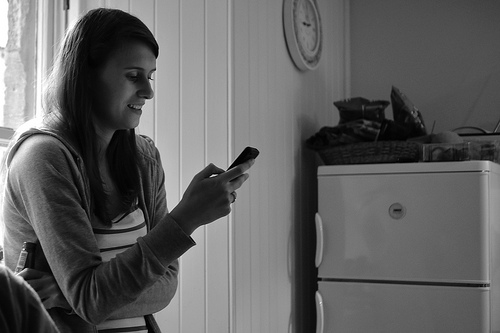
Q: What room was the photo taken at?
A: It was taken at the kitchen.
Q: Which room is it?
A: It is a kitchen.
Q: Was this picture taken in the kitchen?
A: Yes, it was taken in the kitchen.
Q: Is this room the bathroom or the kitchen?
A: It is the kitchen.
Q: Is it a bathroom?
A: No, it is a kitchen.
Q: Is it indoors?
A: Yes, it is indoors.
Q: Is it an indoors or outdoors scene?
A: It is indoors.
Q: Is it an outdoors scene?
A: No, it is indoors.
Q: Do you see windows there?
A: Yes, there is a window.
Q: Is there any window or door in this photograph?
A: Yes, there is a window.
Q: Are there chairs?
A: No, there are no chairs.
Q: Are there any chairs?
A: No, there are no chairs.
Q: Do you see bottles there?
A: Yes, there is a bottle.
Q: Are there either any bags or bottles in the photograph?
A: Yes, there is a bottle.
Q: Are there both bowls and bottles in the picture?
A: No, there is a bottle but no bowls.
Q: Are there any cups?
A: No, there are no cups.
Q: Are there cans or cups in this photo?
A: No, there are no cups or cans.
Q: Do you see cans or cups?
A: No, there are no cups or cans.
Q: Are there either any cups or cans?
A: No, there are no cups or cans.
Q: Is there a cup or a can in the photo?
A: No, there are no cups or cans.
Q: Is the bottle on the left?
A: Yes, the bottle is on the left of the image.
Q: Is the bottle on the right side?
A: No, the bottle is on the left of the image.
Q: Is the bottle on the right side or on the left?
A: The bottle is on the left of the image.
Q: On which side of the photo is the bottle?
A: The bottle is on the left of the image.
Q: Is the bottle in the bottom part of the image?
A: Yes, the bottle is in the bottom of the image.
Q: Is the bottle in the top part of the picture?
A: No, the bottle is in the bottom of the image.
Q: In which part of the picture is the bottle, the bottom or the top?
A: The bottle is in the bottom of the image.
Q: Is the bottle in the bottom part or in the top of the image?
A: The bottle is in the bottom of the image.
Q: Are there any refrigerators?
A: Yes, there is a refrigerator.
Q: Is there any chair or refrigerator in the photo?
A: Yes, there is a refrigerator.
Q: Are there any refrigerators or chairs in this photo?
A: Yes, there is a refrigerator.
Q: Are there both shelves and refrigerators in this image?
A: No, there is a refrigerator but no shelves.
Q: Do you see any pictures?
A: No, there are no pictures.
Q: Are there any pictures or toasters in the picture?
A: No, there are no pictures or toasters.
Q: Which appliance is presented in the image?
A: The appliance is a refrigerator.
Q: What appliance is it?
A: The appliance is a refrigerator.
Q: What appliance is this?
A: This is a refrigerator.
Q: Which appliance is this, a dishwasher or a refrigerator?
A: This is a refrigerator.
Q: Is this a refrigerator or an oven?
A: This is a refrigerator.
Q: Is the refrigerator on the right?
A: Yes, the refrigerator is on the right of the image.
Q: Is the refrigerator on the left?
A: No, the refrigerator is on the right of the image.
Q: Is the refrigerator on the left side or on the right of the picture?
A: The refrigerator is on the right of the image.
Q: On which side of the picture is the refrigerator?
A: The refrigerator is on the right of the image.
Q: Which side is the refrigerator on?
A: The refrigerator is on the right of the image.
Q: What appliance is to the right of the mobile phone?
A: The appliance is a refrigerator.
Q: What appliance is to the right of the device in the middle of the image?
A: The appliance is a refrigerator.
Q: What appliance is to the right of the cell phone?
A: The appliance is a refrigerator.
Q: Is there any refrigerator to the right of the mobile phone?
A: Yes, there is a refrigerator to the right of the mobile phone.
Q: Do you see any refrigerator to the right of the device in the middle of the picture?
A: Yes, there is a refrigerator to the right of the mobile phone.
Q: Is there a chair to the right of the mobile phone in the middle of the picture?
A: No, there is a refrigerator to the right of the cell phone.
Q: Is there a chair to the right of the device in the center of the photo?
A: No, there is a refrigerator to the right of the cell phone.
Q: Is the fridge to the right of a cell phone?
A: Yes, the fridge is to the right of a cell phone.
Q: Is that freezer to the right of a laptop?
A: No, the freezer is to the right of a cell phone.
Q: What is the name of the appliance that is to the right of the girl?
A: The appliance is a refrigerator.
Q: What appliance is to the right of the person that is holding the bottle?
A: The appliance is a refrigerator.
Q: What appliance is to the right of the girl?
A: The appliance is a refrigerator.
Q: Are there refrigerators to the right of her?
A: Yes, there is a refrigerator to the right of the girl.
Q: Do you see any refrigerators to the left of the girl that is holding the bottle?
A: No, the refrigerator is to the right of the girl.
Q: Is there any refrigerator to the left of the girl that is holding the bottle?
A: No, the refrigerator is to the right of the girl.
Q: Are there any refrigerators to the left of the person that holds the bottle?
A: No, the refrigerator is to the right of the girl.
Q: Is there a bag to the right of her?
A: No, there is a refrigerator to the right of the girl.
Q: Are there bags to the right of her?
A: No, there is a refrigerator to the right of the girl.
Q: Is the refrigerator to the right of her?
A: Yes, the refrigerator is to the right of the girl.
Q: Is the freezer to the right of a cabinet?
A: No, the freezer is to the right of the girl.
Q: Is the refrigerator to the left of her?
A: No, the refrigerator is to the right of the girl.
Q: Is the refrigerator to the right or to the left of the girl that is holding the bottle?
A: The refrigerator is to the right of the girl.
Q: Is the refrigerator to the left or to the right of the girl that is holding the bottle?
A: The refrigerator is to the right of the girl.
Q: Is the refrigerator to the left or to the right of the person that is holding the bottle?
A: The refrigerator is to the right of the girl.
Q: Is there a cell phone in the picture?
A: Yes, there is a cell phone.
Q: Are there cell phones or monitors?
A: Yes, there is a cell phone.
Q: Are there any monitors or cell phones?
A: Yes, there is a cell phone.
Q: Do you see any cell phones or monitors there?
A: Yes, there is a cell phone.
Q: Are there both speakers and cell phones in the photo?
A: No, there is a cell phone but no speakers.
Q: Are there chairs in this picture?
A: No, there are no chairs.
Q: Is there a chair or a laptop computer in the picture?
A: No, there are no chairs or laptops.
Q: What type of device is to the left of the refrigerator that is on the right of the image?
A: The device is a cell phone.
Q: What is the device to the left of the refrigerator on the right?
A: The device is a cell phone.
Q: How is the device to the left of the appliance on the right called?
A: The device is a cell phone.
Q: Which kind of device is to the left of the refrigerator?
A: The device is a cell phone.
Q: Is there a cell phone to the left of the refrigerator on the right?
A: Yes, there is a cell phone to the left of the fridge.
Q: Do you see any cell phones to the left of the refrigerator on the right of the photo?
A: Yes, there is a cell phone to the left of the fridge.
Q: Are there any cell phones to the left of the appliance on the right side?
A: Yes, there is a cell phone to the left of the fridge.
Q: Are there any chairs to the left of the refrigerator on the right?
A: No, there is a cell phone to the left of the fridge.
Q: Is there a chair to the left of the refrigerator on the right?
A: No, there is a cell phone to the left of the fridge.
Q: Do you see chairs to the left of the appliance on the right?
A: No, there is a cell phone to the left of the fridge.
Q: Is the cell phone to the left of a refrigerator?
A: Yes, the cell phone is to the left of a refrigerator.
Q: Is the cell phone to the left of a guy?
A: No, the cell phone is to the left of a refrigerator.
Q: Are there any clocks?
A: Yes, there is a clock.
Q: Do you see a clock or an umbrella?
A: Yes, there is a clock.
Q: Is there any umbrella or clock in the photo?
A: Yes, there is a clock.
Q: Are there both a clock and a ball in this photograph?
A: No, there is a clock but no balls.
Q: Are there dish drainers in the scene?
A: No, there are no dish drainers.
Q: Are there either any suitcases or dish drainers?
A: No, there are no dish drainers or suitcases.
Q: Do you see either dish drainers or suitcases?
A: No, there are no dish drainers or suitcases.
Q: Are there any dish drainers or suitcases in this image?
A: No, there are no dish drainers or suitcases.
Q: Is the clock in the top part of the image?
A: Yes, the clock is in the top of the image.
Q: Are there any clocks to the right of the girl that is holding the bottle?
A: Yes, there is a clock to the right of the girl.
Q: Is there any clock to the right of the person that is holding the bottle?
A: Yes, there is a clock to the right of the girl.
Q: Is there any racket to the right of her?
A: No, there is a clock to the right of the girl.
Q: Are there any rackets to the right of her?
A: No, there is a clock to the right of the girl.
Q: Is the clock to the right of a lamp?
A: No, the clock is to the right of a girl.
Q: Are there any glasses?
A: No, there are no glasses.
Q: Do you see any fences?
A: No, there are no fences.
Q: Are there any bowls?
A: No, there are no bowls.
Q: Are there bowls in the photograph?
A: No, there are no bowls.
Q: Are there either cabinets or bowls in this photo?
A: No, there are no bowls or cabinets.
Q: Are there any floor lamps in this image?
A: No, there are no floor lamps.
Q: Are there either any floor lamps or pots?
A: No, there are no floor lamps or pots.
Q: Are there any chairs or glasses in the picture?
A: No, there are no glasses or chairs.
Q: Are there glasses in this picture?
A: No, there are no glasses.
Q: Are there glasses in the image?
A: No, there are no glasses.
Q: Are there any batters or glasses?
A: No, there are no glasses or batters.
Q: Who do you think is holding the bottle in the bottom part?
A: The girl is holding the bottle.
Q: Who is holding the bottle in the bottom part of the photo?
A: The girl is holding the bottle.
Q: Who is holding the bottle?
A: The girl is holding the bottle.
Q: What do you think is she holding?
A: The girl is holding the bottle.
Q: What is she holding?
A: The girl is holding the bottle.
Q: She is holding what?
A: The girl is holding the bottle.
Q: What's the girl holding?
A: The girl is holding the bottle.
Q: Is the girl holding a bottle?
A: Yes, the girl is holding a bottle.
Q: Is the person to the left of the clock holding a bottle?
A: Yes, the girl is holding a bottle.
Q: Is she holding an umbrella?
A: No, the girl is holding a bottle.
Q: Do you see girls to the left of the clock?
A: Yes, there is a girl to the left of the clock.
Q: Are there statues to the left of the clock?
A: No, there is a girl to the left of the clock.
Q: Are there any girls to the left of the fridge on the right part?
A: Yes, there is a girl to the left of the fridge.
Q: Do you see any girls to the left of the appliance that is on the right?
A: Yes, there is a girl to the left of the fridge.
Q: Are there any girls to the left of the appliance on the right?
A: Yes, there is a girl to the left of the fridge.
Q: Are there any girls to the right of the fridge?
A: No, the girl is to the left of the fridge.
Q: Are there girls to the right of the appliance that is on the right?
A: No, the girl is to the left of the fridge.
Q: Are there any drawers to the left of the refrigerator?
A: No, there is a girl to the left of the refrigerator.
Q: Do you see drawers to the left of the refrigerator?
A: No, there is a girl to the left of the refrigerator.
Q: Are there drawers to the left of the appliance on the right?
A: No, there is a girl to the left of the refrigerator.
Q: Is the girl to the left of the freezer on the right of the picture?
A: Yes, the girl is to the left of the refrigerator.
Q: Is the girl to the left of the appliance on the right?
A: Yes, the girl is to the left of the refrigerator.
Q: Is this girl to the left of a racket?
A: No, the girl is to the left of the refrigerator.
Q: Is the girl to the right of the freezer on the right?
A: No, the girl is to the left of the fridge.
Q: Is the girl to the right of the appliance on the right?
A: No, the girl is to the left of the fridge.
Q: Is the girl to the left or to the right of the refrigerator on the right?
A: The girl is to the left of the fridge.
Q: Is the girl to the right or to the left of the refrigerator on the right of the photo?
A: The girl is to the left of the fridge.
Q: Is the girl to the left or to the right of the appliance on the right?
A: The girl is to the left of the fridge.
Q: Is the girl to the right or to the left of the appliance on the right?
A: The girl is to the left of the fridge.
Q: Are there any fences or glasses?
A: No, there are no glasses or fences.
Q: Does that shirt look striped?
A: Yes, the shirt is striped.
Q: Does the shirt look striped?
A: Yes, the shirt is striped.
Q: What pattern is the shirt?
A: The shirt is striped.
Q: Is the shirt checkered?
A: No, the shirt is striped.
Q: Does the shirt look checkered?
A: No, the shirt is striped.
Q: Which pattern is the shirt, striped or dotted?
A: The shirt is striped.